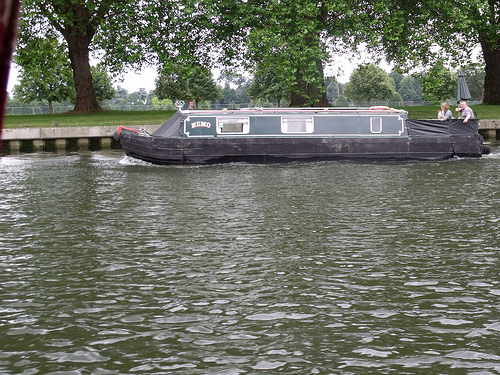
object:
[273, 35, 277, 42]
leaves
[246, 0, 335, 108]
tree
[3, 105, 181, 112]
fence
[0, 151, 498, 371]
water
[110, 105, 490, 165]
boat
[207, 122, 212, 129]
word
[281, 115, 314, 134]
window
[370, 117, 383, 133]
window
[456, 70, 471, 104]
umbrella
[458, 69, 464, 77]
top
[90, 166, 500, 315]
ripple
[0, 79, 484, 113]
park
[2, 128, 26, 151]
structure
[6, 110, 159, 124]
grass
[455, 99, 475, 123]
man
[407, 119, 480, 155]
back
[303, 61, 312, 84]
branches